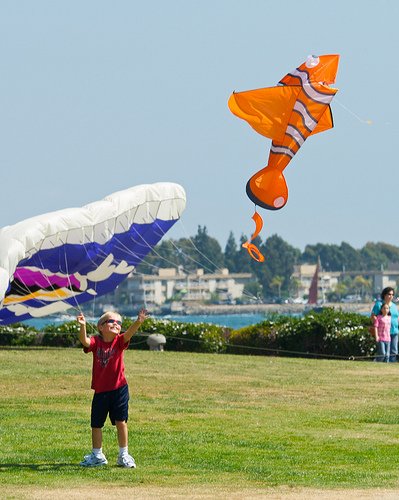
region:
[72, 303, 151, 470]
the boy standing on the grass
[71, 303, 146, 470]
the boy reaching for a kite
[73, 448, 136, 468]
the shoes on the boy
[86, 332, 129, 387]
the boy's red shirt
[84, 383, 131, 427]
the boy's dark shorts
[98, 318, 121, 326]
the boy's red sunglasses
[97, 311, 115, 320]
the boy's blond hair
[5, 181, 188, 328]
the kite above the boy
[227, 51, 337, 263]
the orange fish kite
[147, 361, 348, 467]
the short green grass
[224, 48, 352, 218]
orange kite shaped like fish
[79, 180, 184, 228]
white edge of kite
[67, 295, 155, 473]
child holding kite strings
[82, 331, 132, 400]
red short sleeved shirt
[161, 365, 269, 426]
green grass cut short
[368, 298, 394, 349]
girl in pink shirt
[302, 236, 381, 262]
tree tops on horizon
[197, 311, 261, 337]
blue water behind bush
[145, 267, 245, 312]
white building overlooking water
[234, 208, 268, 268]
orange tail on kite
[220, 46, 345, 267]
clown fish kite in flight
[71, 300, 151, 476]
little boy reaching for kite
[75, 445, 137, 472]
sneakers on little boy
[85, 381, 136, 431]
black shorts on little boy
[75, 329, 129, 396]
red shirt on little boy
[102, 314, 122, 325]
sunglasses on little boy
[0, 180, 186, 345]
miniature parachute in boy's hand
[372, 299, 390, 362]
little girl in pink shirt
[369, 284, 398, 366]
woman and child watching kites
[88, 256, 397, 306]
hotel across the lake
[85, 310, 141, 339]
Boy wearing sunglasses.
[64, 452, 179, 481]
Boy wearing white shoes.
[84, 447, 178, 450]
Boy wearing white socks.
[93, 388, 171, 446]
Boy wearing blue shorts.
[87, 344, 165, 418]
Boy wearing red shirt.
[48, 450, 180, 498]
Boy standing in grass.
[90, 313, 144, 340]
Boy has blonde hair.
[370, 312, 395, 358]
Person wearing pink shirt.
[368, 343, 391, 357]
Girl wearing blue jeans.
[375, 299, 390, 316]
Woman wearing large blue shirt.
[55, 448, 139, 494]
white sneakers and socks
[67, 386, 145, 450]
a pair of blue shorts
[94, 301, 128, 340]
person in red sunglasses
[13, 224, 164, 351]
child flying a kite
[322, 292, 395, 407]
woman in blue with girl in pink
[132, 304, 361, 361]
green bushesby the water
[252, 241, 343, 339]
a sail boat on the water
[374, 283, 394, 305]
a woman with sunglasses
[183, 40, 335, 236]
orange and white fish kite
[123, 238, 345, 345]
buildings by the water